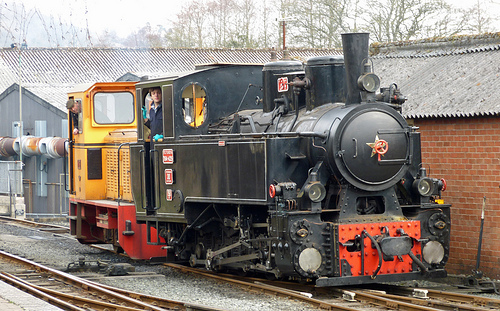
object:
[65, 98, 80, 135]
men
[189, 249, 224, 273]
wheels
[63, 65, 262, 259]
train car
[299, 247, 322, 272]
light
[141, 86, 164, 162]
man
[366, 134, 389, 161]
image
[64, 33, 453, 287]
train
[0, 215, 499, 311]
gravel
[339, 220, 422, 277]
plate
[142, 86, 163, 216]
door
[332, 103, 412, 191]
circle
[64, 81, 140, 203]
cab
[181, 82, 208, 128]
openings